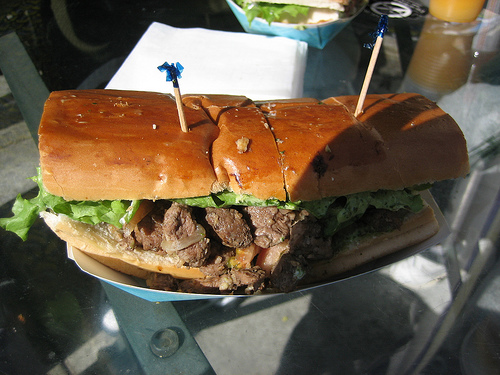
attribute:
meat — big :
[134, 205, 322, 262]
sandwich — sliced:
[68, 104, 283, 174]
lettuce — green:
[6, 183, 141, 233]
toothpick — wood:
[141, 54, 201, 128]